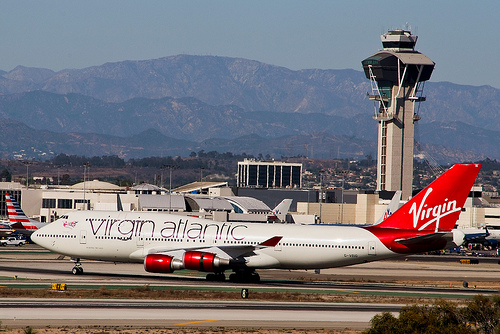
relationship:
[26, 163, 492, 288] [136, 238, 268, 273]
plane has wing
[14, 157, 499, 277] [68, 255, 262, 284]
planes has wheels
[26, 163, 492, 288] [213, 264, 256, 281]
plane has wheels